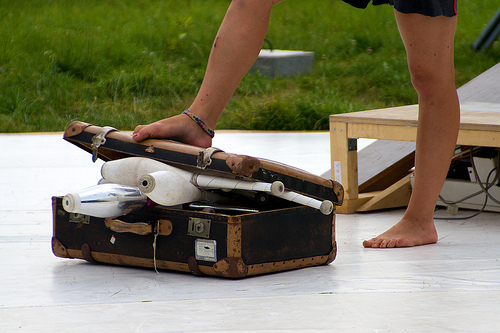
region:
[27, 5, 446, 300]
A person is standing on a box.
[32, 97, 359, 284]
The box lid is open.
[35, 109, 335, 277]
The box contains juggling pins.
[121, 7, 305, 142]
A person wears an ankle bracelet.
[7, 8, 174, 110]
The grass is green.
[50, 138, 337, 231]
The juggling pins are silver and white.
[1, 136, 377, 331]
The floor is white.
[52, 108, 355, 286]
The box is brown.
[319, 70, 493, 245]
The person stands in front of a bench.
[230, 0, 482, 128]
The person wears shorts.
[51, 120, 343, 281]
an old black and tan suitcase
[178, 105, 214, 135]
a blue, yellow, and orange ankle bracelet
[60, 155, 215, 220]
three white colored juggling pins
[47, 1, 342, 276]
a person's foot on a suitcase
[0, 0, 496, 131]
tall green colored grass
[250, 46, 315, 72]
concrete square in the background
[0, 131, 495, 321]
white concrete floor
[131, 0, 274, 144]
a person's right leg with a small cut on the front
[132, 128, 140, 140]
red painted toenail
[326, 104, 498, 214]
a wooden platform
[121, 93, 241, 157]
foot of the person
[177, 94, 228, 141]
bracelet around foot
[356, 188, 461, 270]
left foot of a person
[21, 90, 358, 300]
suitcase under a person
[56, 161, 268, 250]
items in the suitcase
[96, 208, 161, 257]
handle of the suitcase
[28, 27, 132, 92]
green grass in the background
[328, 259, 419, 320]
ground under the person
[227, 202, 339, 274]
side of the suitcase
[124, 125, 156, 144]
big toe of person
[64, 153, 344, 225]
white and black juggling pins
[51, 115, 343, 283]
black and bronze suitcase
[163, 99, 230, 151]
braided cloth bracelet on ankle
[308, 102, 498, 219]
wooden platform with unfinished wood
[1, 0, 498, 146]
green grass beside white sidewalk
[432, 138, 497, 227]
gray electrical cords under stage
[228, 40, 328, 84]
metal box in green grass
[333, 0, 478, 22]
blue and red athletic shorts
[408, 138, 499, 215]
white and black electrical equipment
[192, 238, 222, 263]
white and silver information tag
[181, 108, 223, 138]
Band on a person's ankle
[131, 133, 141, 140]
Toe nail painted pink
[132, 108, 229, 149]
Person's left foot on a trunk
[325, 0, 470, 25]
Person wearing black shorts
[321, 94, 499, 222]
Wooden bench behind a person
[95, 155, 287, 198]
Bowling pin with a long neck for juggling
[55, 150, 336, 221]
Bowling pins in a trunk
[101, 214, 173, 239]
Leather handle on a trunk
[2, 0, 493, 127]
Green grass in a yard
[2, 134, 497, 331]
Person standing on a white platform